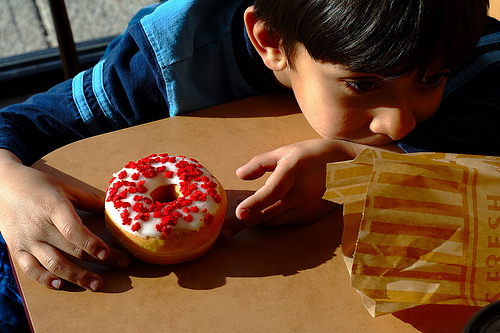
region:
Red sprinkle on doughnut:
[125, 219, 146, 236]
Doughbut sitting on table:
[92, 138, 244, 295]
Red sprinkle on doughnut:
[120, 211, 133, 228]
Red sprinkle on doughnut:
[115, 195, 129, 207]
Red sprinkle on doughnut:
[178, 211, 187, 233]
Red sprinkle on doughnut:
[200, 202, 211, 224]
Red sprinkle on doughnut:
[173, 196, 198, 226]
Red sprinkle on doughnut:
[198, 174, 220, 205]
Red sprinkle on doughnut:
[144, 142, 174, 169]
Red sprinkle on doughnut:
[126, 156, 153, 172]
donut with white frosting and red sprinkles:
[111, 152, 224, 257]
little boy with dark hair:
[244, 0, 489, 148]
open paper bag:
[328, 150, 498, 316]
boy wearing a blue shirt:
[5, 0, 495, 155]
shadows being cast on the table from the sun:
[219, 235, 321, 288]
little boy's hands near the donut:
[17, 147, 329, 290]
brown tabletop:
[38, 294, 353, 328]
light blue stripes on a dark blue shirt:
[71, 61, 120, 133]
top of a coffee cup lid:
[461, 297, 498, 329]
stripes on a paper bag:
[376, 154, 451, 302]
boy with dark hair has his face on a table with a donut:
[75, 7, 439, 292]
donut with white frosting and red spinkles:
[102, 146, 224, 265]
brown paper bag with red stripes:
[325, 140, 493, 320]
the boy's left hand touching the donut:
[5, 147, 106, 309]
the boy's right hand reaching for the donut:
[230, 127, 327, 234]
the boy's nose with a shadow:
[370, 104, 421, 141]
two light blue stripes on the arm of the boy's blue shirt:
[63, 58, 126, 130]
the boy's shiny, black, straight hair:
[305, 7, 459, 66]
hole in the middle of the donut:
[146, 182, 188, 201]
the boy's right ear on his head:
[238, 4, 292, 76]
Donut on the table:
[57, 131, 279, 286]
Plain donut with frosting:
[84, 140, 246, 270]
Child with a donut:
[4, 9, 492, 325]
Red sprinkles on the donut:
[115, 137, 205, 238]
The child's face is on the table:
[241, 0, 448, 155]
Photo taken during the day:
[10, 8, 492, 323]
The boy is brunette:
[230, 0, 499, 82]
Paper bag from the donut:
[331, 133, 488, 319]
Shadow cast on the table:
[88, 188, 343, 291]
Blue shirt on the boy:
[19, 18, 196, 175]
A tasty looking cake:
[108, 153, 228, 260]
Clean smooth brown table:
[183, 288, 337, 327]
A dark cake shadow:
[231, 236, 303, 264]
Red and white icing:
[122, 200, 168, 227]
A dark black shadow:
[225, 232, 280, 267]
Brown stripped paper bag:
[322, 131, 492, 317]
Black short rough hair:
[297, 10, 488, 76]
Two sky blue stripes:
[66, 55, 121, 120]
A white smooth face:
[292, 80, 449, 135]